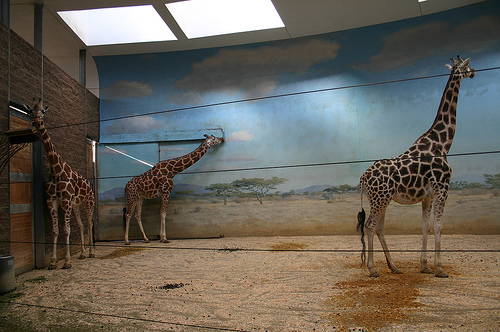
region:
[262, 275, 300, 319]
part of a ground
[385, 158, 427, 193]
stomach of a giraffe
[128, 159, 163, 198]
part of a stomach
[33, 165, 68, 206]
chest of a giraffe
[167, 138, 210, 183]
neck of a giraffe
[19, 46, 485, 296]
THREE GIRAFFES IN CAPTIVITY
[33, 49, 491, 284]
THREE GIRAFFES IN A ROOM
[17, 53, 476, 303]
THREE GIRAFFES AT THE ZOO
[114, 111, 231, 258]
THE GIRAFFE IN THE MIDDLE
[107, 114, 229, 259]
THE GIRAFFE PUTTING HIS NOSE IN THE SKY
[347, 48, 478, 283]
THE GIRAFFE WITH THE WIRY LONG BROWN TAIL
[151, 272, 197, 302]
A PILE OF GIRAFFE POOP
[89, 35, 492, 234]
A BACKDROP OF A FAKE SAVANAH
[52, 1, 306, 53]
THE CEILING LIGHTS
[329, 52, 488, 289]
THE CLOSEST, BIGGEST GIRAFFE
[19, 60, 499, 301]
there are three giraffes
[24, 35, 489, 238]
the giraffes are inside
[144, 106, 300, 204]
the wall has been painted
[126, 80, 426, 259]
the enclosure has a safari mural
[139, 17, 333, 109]
the enclosure has a skylight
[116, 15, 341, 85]
two windows for skylight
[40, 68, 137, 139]
the wall is brick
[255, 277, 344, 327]
the dirt is tan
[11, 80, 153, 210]
this giraffe faces camera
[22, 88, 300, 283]
giraffes have spotted coats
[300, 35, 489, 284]
the right brown giraffe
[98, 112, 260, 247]
the center brown giraffe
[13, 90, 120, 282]
the left brown giraffe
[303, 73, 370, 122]
this is the sky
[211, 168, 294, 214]
these are two trees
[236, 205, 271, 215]
this is the savannah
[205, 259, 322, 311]
this is brown dirt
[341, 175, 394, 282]
this is a giraffe's tail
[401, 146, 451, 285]
these are the giraffe's front legs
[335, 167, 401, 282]
these are the giraffe's back legs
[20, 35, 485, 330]
Three giraffes in barn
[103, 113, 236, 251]
Giraffe is close to wall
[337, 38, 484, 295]
Giraffe in barn is big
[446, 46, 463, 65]
Horns of giraffe on top of head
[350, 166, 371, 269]
Tail of giraffe is long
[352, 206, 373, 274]
Turf of giraffe is black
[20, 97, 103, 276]
giraffe is next to a door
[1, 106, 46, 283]
Door is orange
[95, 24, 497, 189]
Blue sky is painted in wall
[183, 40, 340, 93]
White clouds painted on wall